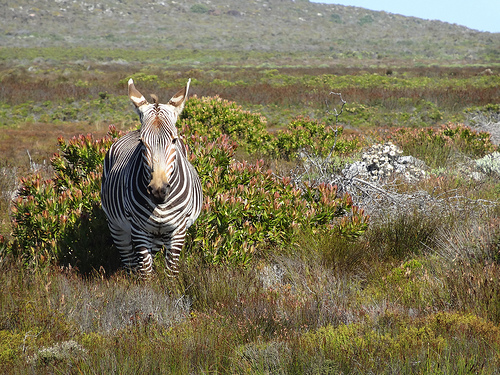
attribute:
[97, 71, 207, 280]
zebra — black 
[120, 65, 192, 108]
ears —  perky 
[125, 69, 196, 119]
ears —  black ,  white 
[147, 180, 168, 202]
snout —  brown ,  black 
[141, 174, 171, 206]
nostril — large black 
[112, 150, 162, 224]
stripes — white 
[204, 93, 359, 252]
bushes — green 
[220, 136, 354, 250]
flowers — white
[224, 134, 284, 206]
bushes — brown  , growing  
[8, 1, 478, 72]
hill — small 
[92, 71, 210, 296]
zebra — white , black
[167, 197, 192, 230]
stripes — brown , white 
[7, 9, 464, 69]
hill — small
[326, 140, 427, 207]
rocks — white  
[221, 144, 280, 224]
flowers — pink 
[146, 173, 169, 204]
nose — black 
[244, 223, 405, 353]
grass — tall 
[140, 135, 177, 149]
eye — small 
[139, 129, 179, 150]
eye — small 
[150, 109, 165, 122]
hair — small red